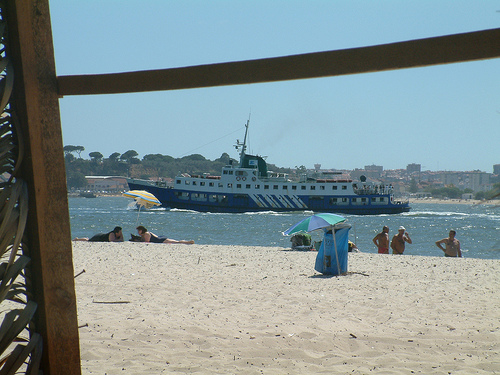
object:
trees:
[61, 142, 87, 173]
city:
[342, 158, 499, 200]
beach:
[408, 195, 499, 206]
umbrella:
[273, 207, 357, 283]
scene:
[0, 125, 499, 371]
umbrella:
[112, 184, 167, 243]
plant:
[0, 2, 40, 375]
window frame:
[0, 0, 499, 375]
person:
[126, 221, 197, 251]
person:
[66, 221, 128, 248]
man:
[426, 227, 468, 264]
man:
[369, 223, 393, 258]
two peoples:
[67, 217, 199, 250]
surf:
[414, 206, 498, 226]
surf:
[67, 204, 180, 215]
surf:
[242, 208, 318, 218]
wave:
[173, 207, 231, 218]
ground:
[172, 289, 263, 349]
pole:
[349, 219, 362, 257]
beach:
[0, 239, 496, 373]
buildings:
[380, 163, 399, 184]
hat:
[391, 224, 411, 234]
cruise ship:
[113, 99, 416, 222]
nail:
[66, 267, 91, 283]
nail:
[77, 318, 91, 338]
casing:
[1, 0, 96, 374]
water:
[211, 227, 250, 236]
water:
[468, 221, 499, 254]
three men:
[363, 220, 471, 263]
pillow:
[126, 230, 147, 245]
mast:
[231, 105, 256, 178]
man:
[385, 220, 419, 259]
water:
[84, 197, 102, 215]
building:
[403, 160, 419, 198]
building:
[431, 167, 451, 188]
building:
[450, 167, 470, 188]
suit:
[135, 229, 172, 249]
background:
[413, 159, 499, 207]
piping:
[114, 186, 167, 215]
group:
[363, 219, 470, 262]